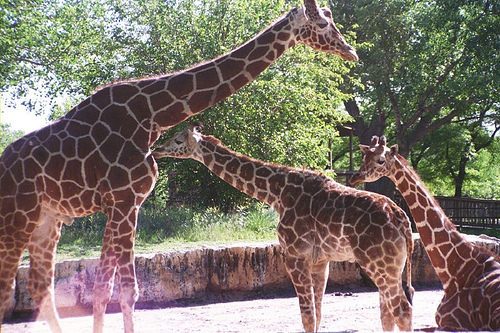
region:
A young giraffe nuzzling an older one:
[157, 123, 418, 330]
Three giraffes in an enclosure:
[1, 0, 498, 330]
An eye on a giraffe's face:
[315, 17, 327, 29]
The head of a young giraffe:
[346, 132, 401, 185]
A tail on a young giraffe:
[393, 215, 420, 303]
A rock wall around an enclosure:
[4, 230, 499, 313]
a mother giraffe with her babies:
[0, 0, 359, 331]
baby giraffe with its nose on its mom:
[152, 121, 414, 331]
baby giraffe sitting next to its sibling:
[350, 134, 499, 331]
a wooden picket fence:
[392, 196, 498, 233]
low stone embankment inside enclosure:
[0, 236, 497, 312]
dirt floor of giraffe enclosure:
[13, 288, 497, 331]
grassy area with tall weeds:
[59, 204, 274, 261]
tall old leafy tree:
[334, 0, 498, 185]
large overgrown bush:
[94, 0, 357, 215]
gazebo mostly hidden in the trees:
[336, 86, 358, 181]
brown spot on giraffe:
[58, 130, 66, 138]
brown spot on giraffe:
[1, 168, 17, 197]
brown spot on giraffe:
[272, 222, 297, 247]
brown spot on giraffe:
[278, 182, 298, 207]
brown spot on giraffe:
[315, 206, 337, 222]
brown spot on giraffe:
[392, 168, 403, 181]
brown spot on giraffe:
[405, 182, 415, 189]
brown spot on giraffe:
[406, 202, 425, 224]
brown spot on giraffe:
[66, 117, 92, 138]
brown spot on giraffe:
[91, 121, 108, 145]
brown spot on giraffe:
[113, 137, 146, 170]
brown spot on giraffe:
[254, 165, 274, 177]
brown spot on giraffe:
[252, 173, 269, 191]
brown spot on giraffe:
[255, 189, 269, 204]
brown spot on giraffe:
[396, 177, 410, 193]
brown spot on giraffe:
[415, 191, 431, 209]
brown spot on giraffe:
[415, 223, 436, 249]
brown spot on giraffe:
[447, 242, 463, 275]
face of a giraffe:
[307, 5, 362, 71]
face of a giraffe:
[165, 122, 210, 167]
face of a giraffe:
[350, 140, 410, 182]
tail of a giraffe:
[395, 207, 420, 285]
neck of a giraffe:
[403, 173, 449, 236]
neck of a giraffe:
[210, 147, 282, 203]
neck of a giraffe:
[206, 25, 269, 105]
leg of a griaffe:
[273, 251, 314, 328]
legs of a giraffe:
[380, 291, 436, 331]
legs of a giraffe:
[94, 207, 158, 332]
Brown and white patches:
[66, 127, 128, 206]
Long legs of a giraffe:
[80, 217, 160, 324]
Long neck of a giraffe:
[169, 53, 269, 88]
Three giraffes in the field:
[74, 74, 461, 295]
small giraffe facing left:
[342, 133, 498, 331]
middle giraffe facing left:
[149, 123, 427, 331]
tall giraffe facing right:
[2, 3, 369, 332]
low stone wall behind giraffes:
[1, 229, 498, 324]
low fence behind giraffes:
[362, 181, 497, 244]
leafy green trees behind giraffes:
[5, 2, 498, 238]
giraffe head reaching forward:
[144, 114, 213, 171]